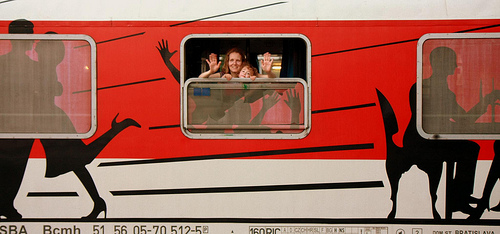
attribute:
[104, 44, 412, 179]
background — red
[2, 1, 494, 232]
wall — red and white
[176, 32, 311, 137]
window — rectangular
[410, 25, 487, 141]
window — three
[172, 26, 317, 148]
window — three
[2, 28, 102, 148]
window — three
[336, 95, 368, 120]
line — black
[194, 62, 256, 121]
child — young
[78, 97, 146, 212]
heel — black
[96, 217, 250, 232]
lettering — black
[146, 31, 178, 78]
hand — black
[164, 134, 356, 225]
line — black